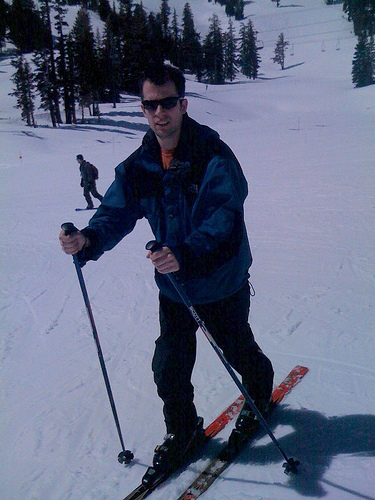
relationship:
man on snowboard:
[76, 154, 105, 210] [71, 202, 101, 212]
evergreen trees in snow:
[0, 0, 375, 128] [4, 2, 372, 334]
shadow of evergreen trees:
[69, 107, 142, 133] [0, 0, 375, 128]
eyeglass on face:
[141, 95, 185, 111] [136, 71, 189, 141]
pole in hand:
[58, 221, 134, 466] [58, 229, 86, 256]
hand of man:
[58, 229, 86, 256] [57, 66, 275, 466]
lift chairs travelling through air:
[287, 35, 356, 58] [0, 91, 373, 138]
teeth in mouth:
[158, 121, 168, 123] [154, 118, 170, 126]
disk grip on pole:
[112, 444, 136, 465] [58, 221, 134, 466]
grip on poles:
[280, 454, 299, 477] [144, 240, 302, 477]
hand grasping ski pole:
[145, 249, 179, 275] [51, 213, 141, 471]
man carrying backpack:
[72, 154, 101, 209] [89, 161, 98, 180]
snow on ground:
[247, 122, 364, 272] [5, 83, 370, 498]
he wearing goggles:
[58, 63, 274, 483] [139, 92, 184, 113]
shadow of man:
[263, 406, 373, 496] [57, 66, 275, 466]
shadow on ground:
[263, 406, 373, 496] [5, 83, 370, 498]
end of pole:
[117, 450, 135, 466] [58, 221, 136, 465]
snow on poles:
[0, 0, 375, 500] [144, 240, 302, 477]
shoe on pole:
[151, 429, 189, 469] [65, 248, 137, 466]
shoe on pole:
[235, 403, 255, 428] [65, 248, 137, 466]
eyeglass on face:
[141, 95, 185, 111] [141, 81, 183, 136]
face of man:
[141, 81, 183, 136] [57, 66, 275, 466]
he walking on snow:
[58, 63, 274, 475] [0, 83, 375, 494]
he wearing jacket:
[58, 63, 274, 475] [102, 138, 247, 307]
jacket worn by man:
[81, 123, 249, 299] [65, 57, 277, 442]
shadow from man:
[169, 401, 375, 500] [57, 66, 275, 466]